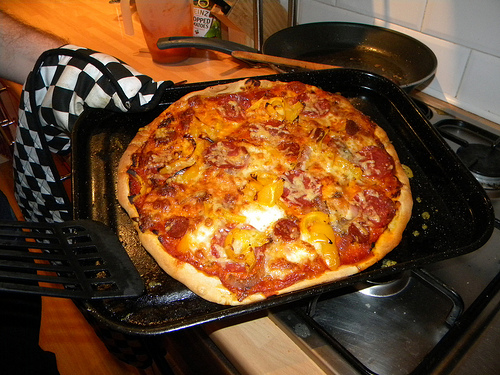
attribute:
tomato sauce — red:
[227, 273, 302, 294]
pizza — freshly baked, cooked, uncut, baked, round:
[116, 78, 413, 306]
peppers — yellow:
[300, 210, 339, 270]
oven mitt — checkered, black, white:
[12, 44, 174, 290]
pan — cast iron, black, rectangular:
[68, 67, 497, 338]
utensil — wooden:
[230, 47, 343, 71]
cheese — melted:
[241, 204, 284, 231]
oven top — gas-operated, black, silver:
[276, 98, 498, 373]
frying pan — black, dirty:
[144, 20, 438, 94]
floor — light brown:
[0, 161, 145, 372]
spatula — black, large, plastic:
[1, 217, 145, 301]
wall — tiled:
[297, 0, 500, 125]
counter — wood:
[1, 0, 278, 100]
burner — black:
[285, 256, 499, 374]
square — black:
[74, 71, 97, 101]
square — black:
[52, 84, 74, 113]